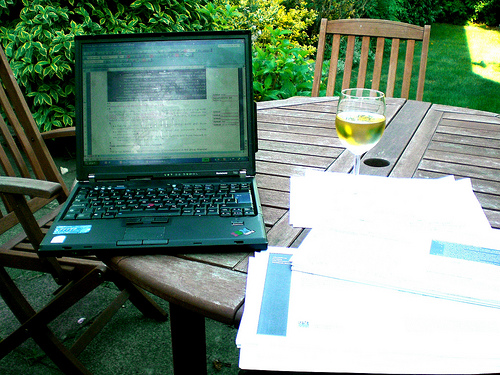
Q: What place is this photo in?
A: It is at the backyard.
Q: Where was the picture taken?
A: It was taken at the backyard.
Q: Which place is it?
A: It is a backyard.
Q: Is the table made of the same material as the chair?
A: Yes, both the table and the chair are made of wood.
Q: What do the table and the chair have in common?
A: The material, both the table and the chair are wooden.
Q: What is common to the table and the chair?
A: The material, both the table and the chair are wooden.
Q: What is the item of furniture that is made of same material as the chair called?
A: The piece of furniture is a table.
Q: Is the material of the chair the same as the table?
A: Yes, both the chair and the table are made of wood.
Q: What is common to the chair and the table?
A: The material, both the chair and the table are wooden.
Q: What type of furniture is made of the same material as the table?
A: The chair is made of the same material as the table.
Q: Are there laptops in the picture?
A: Yes, there is a laptop.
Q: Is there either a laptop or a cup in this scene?
A: Yes, there is a laptop.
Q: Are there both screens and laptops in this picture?
A: Yes, there are both a laptop and a screen.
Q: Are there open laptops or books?
A: Yes, there is an open laptop.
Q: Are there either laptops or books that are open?
A: Yes, the laptop is open.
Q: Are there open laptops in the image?
A: Yes, there is an open laptop.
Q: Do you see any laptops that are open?
A: Yes, there is a laptop that is open.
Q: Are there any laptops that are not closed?
A: Yes, there is a open laptop.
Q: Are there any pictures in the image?
A: No, there are no pictures.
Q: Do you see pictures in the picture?
A: No, there are no pictures.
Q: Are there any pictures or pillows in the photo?
A: No, there are no pictures or pillows.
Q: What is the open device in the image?
A: The device is a laptop.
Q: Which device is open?
A: The device is a laptop.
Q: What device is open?
A: The device is a laptop.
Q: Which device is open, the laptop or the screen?
A: The laptop is open.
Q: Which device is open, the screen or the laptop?
A: The laptop is open.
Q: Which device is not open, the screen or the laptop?
A: The screen is not open.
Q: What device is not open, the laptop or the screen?
A: The screen is not open.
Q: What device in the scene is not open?
A: The device is a screen.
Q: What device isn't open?
A: The device is a screen.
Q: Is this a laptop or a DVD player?
A: This is a laptop.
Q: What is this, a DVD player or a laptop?
A: This is a laptop.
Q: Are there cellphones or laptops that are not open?
A: No, there is a laptop but it is open.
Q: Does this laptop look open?
A: Yes, the laptop is open.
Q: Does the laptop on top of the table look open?
A: Yes, the laptop is open.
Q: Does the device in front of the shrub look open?
A: Yes, the laptop is open.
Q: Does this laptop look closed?
A: No, the laptop is open.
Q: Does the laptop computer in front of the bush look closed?
A: No, the laptop is open.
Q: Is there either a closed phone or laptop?
A: No, there is a laptop but it is open.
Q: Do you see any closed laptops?
A: No, there is a laptop but it is open.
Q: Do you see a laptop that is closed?
A: No, there is a laptop but it is open.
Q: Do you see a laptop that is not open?
A: No, there is a laptop but it is open.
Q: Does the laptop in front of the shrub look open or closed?
A: The laptop computer is open.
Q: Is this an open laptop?
A: Yes, this is an open laptop.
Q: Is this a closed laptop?
A: No, this is an open laptop.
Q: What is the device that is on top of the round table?
A: The device is a laptop.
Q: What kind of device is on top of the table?
A: The device is a laptop.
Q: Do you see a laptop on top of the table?
A: Yes, there is a laptop on top of the table.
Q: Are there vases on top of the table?
A: No, there is a laptop on top of the table.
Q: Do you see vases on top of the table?
A: No, there is a laptop on top of the table.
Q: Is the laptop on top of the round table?
A: Yes, the laptop is on top of the table.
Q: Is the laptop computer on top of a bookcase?
A: No, the laptop computer is on top of the table.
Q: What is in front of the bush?
A: The laptop is in front of the shrub.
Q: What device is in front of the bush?
A: The device is a laptop.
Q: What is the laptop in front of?
A: The laptop is in front of the bush.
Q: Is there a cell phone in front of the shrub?
A: No, there is a laptop in front of the shrub.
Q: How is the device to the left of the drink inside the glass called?
A: The device is a laptop.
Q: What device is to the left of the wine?
A: The device is a laptop.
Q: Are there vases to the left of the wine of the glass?
A: No, there is a laptop to the left of the wine.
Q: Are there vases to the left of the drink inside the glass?
A: No, there is a laptop to the left of the wine.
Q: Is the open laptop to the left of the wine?
A: Yes, the laptop is to the left of the wine.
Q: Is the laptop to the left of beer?
A: No, the laptop is to the left of the wine.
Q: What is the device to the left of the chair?
A: The device is a laptop.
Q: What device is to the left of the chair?
A: The device is a laptop.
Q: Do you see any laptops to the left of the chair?
A: Yes, there is a laptop to the left of the chair.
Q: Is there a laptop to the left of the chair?
A: Yes, there is a laptop to the left of the chair.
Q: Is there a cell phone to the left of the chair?
A: No, there is a laptop to the left of the chair.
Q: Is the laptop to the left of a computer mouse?
A: No, the laptop is to the left of the chair.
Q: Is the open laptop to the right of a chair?
A: No, the laptop computer is to the left of a chair.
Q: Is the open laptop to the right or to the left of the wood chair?
A: The laptop computer is to the left of the chair.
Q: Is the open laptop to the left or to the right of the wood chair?
A: The laptop computer is to the left of the chair.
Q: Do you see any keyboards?
A: Yes, there is a keyboard.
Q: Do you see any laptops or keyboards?
A: Yes, there is a keyboard.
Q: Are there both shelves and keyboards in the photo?
A: No, there is a keyboard but no shelves.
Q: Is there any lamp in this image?
A: No, there are no lamps.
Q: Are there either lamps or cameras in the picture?
A: No, there are no lamps or cameras.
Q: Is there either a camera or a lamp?
A: No, there are no lamps or cameras.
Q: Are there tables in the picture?
A: Yes, there is a table.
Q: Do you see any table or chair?
A: Yes, there is a table.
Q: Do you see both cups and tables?
A: No, there is a table but no cups.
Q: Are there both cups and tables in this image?
A: No, there is a table but no cups.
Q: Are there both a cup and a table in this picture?
A: No, there is a table but no cups.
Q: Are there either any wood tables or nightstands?
A: Yes, there is a wood table.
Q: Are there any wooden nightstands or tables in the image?
A: Yes, there is a wood table.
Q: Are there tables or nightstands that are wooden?
A: Yes, the table is wooden.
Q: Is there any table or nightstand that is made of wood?
A: Yes, the table is made of wood.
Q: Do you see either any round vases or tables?
A: Yes, there is a round table.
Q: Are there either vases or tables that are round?
A: Yes, the table is round.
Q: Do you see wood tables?
A: Yes, there is a table that is made of wood.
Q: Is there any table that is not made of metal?
A: Yes, there is a table that is made of wood.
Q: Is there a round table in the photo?
A: Yes, there is a round table.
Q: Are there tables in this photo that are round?
A: Yes, there is a round table.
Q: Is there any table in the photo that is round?
A: Yes, there is a table that is round.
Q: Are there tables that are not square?
A: Yes, there is a round table.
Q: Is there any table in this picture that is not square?
A: Yes, there is a round table.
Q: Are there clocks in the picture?
A: No, there are no clocks.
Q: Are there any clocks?
A: No, there are no clocks.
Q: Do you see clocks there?
A: No, there are no clocks.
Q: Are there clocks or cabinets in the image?
A: No, there are no clocks or cabinets.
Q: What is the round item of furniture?
A: The piece of furniture is a table.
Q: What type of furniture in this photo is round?
A: The furniture is a table.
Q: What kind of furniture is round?
A: The furniture is a table.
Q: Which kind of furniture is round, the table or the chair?
A: The table is round.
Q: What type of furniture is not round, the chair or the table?
A: The chair is not round.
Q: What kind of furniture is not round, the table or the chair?
A: The chair is not round.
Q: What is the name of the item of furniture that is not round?
A: The piece of furniture is a chair.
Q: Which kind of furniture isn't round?
A: The furniture is a chair.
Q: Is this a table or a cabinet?
A: This is a table.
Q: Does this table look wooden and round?
A: Yes, the table is wooden and round.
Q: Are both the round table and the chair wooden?
A: Yes, both the table and the chair are wooden.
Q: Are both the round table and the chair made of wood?
A: Yes, both the table and the chair are made of wood.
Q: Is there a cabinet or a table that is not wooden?
A: No, there is a table but it is wooden.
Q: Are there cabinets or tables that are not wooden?
A: No, there is a table but it is wooden.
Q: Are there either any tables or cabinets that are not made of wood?
A: No, there is a table but it is made of wood.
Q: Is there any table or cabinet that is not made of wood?
A: No, there is a table but it is made of wood.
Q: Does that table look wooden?
A: Yes, the table is wooden.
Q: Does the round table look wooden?
A: Yes, the table is wooden.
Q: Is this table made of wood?
A: Yes, the table is made of wood.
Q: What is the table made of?
A: The table is made of wood.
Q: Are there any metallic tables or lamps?
A: No, there is a table but it is wooden.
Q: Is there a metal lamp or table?
A: No, there is a table but it is wooden.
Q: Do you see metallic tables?
A: No, there is a table but it is wooden.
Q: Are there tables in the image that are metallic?
A: No, there is a table but it is wooden.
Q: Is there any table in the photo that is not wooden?
A: No, there is a table but it is wooden.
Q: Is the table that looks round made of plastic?
A: No, the table is made of wood.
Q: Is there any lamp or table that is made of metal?
A: No, there is a table but it is made of wood.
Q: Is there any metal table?
A: No, there is a table but it is made of wood.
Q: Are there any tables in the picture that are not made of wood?
A: No, there is a table but it is made of wood.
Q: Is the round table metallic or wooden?
A: The table is wooden.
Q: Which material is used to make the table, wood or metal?
A: The table is made of wood.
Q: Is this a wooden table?
A: Yes, this is a wooden table.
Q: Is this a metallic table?
A: No, this is a wooden table.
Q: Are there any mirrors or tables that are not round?
A: No, there is a table but it is round.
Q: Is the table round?
A: Yes, the table is round.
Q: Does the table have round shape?
A: Yes, the table is round.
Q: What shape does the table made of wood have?
A: The table has round shape.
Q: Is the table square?
A: No, the table is round.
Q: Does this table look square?
A: No, the table is round.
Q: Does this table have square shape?
A: No, the table is round.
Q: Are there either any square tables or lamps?
A: No, there is a table but it is round.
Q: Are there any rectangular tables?
A: No, there is a table but it is round.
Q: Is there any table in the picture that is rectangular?
A: No, there is a table but it is round.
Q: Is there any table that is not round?
A: No, there is a table but it is round.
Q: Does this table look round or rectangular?
A: The table is round.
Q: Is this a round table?
A: Yes, this is a round table.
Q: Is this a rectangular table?
A: No, this is a round table.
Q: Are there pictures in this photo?
A: No, there are no pictures.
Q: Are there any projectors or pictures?
A: No, there are no pictures or projectors.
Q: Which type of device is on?
A: The device is a screen.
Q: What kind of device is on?
A: The device is a screen.